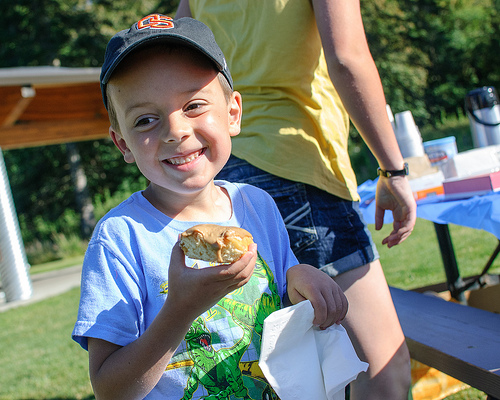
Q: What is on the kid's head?
A: Hat.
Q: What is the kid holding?
A: Donut.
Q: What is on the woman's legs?
A: Denim shorts.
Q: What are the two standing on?
A: Grass.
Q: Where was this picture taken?
A: In a park.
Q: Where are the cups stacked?
A: On the table.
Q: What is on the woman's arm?
A: Wristwatch.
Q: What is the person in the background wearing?
A: Person in the background is wearing a watch.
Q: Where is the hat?
A: Hat sits on head.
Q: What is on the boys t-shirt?
A: Boy wears shirt with dinosaur on it.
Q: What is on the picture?
A: A smiling face of a boy.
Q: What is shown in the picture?
A: A shadow of the bill of the cap.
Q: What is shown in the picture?
A: A roof for shade.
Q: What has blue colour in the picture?
A: The boy has a blue cap.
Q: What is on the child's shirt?
A: Two dinosaurs.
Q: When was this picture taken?
A: During the afternoon.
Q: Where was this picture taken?
A: At a park.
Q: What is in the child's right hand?
A: A donut.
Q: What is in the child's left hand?
A: A napkin.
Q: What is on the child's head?
A: A hat.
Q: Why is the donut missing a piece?
A: The boy has been eating it.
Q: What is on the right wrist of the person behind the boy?
A: A small wrist watch.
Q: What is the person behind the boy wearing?
A: A yellow shirt and shorts.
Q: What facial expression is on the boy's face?
A: A smile.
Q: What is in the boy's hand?
A: Pastry.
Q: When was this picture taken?
A: During the day.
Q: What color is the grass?
A: Green.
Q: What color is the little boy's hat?
A: Blue.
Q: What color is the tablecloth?
A: Blue.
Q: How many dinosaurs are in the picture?
A: Zero.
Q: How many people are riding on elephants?
A: Zero.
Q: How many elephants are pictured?
A: Zero.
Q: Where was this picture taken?
A: In a park.